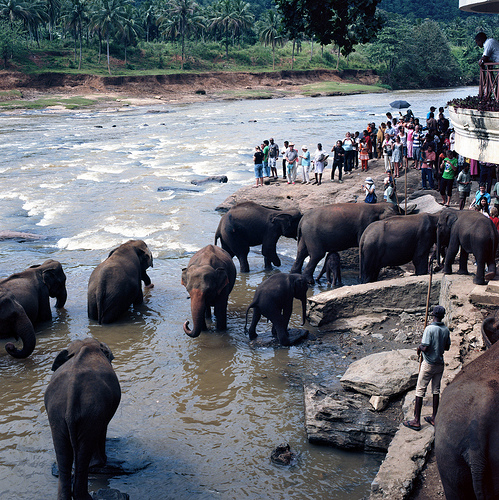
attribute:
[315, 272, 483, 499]
boulders — large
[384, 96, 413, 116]
rock — large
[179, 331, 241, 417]
reflection — of elephant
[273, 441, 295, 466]
rock — small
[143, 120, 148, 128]
rock — small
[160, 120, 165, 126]
rock — small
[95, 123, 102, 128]
rock — small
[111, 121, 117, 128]
rock — small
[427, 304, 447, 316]
hair — short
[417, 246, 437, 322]
pole — thin, wooden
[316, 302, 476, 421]
rock — flat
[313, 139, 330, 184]
person — crowd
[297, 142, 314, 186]
person — crowd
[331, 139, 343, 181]
person — crowd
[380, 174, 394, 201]
person — crowd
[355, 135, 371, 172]
person — crowd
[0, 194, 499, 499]
elephants — gray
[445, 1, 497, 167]
building — white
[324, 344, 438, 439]
rock — large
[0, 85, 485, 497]
river — blue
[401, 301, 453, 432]
tender — elephant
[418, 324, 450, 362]
shirt — blue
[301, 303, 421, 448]
ledge — rocks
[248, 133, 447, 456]
bank — river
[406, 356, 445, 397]
pants — tan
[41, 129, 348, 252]
rapids — river